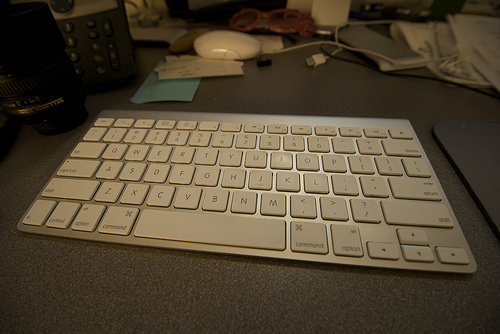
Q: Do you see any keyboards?
A: Yes, there is a keyboard.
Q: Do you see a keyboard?
A: Yes, there is a keyboard.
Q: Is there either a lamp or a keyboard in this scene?
A: Yes, there is a keyboard.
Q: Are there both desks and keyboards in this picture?
A: Yes, there are both a keyboard and a desk.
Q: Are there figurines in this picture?
A: No, there are no figurines.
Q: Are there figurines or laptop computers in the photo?
A: No, there are no figurines or laptop computers.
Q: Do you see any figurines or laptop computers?
A: No, there are no figurines or laptop computers.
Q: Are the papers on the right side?
A: Yes, the papers are on the right of the image.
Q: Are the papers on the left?
A: No, the papers are on the right of the image.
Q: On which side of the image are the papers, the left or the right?
A: The papers are on the right of the image.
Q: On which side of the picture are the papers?
A: The papers are on the right of the image.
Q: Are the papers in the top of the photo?
A: Yes, the papers are in the top of the image.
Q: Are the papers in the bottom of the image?
A: No, the papers are in the top of the image.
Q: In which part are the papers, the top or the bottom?
A: The papers are in the top of the image.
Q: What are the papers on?
A: The papers are on the desk.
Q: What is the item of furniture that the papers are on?
A: The piece of furniture is a desk.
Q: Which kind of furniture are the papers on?
A: The papers are on the desk.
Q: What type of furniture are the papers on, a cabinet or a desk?
A: The papers are on a desk.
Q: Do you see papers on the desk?
A: Yes, there are papers on the desk.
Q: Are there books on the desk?
A: No, there are papers on the desk.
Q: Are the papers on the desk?
A: Yes, the papers are on the desk.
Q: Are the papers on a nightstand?
A: No, the papers are on the desk.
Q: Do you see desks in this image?
A: Yes, there is a desk.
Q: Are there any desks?
A: Yes, there is a desk.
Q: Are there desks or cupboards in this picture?
A: Yes, there is a desk.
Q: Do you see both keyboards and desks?
A: Yes, there are both a desk and a keyboard.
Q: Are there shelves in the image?
A: No, there are no shelves.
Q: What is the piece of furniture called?
A: The piece of furniture is a desk.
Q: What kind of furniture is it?
A: The piece of furniture is a desk.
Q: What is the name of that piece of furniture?
A: This is a desk.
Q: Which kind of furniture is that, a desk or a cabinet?
A: This is a desk.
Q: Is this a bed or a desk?
A: This is a desk.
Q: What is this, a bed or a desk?
A: This is a desk.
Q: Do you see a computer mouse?
A: Yes, there is a computer mouse.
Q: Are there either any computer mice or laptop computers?
A: Yes, there is a computer mouse.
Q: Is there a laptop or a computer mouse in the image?
A: Yes, there is a computer mouse.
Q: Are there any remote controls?
A: No, there are no remote controls.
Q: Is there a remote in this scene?
A: No, there are no remote controls.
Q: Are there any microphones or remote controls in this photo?
A: No, there are no remote controls or microphones.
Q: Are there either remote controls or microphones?
A: No, there are no remote controls or microphones.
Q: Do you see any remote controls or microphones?
A: No, there are no remote controls or microphones.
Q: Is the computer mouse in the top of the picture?
A: Yes, the computer mouse is in the top of the image.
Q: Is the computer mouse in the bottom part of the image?
A: No, the computer mouse is in the top of the image.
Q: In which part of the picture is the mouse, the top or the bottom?
A: The mouse is in the top of the image.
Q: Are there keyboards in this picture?
A: Yes, there is a keyboard.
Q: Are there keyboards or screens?
A: Yes, there is a keyboard.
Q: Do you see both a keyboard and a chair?
A: No, there is a keyboard but no chairs.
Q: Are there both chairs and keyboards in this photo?
A: No, there is a keyboard but no chairs.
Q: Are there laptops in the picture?
A: No, there are no laptops.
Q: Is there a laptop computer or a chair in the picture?
A: No, there are no laptops or chairs.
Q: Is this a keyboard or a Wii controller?
A: This is a keyboard.